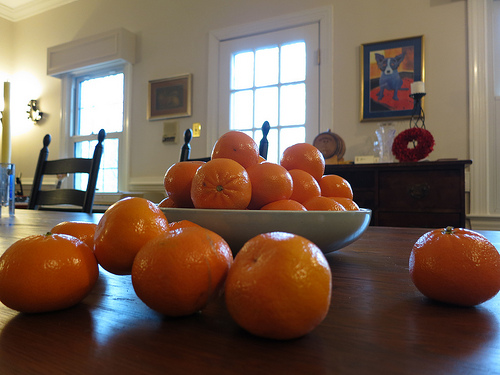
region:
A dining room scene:
[9, 11, 498, 367]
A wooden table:
[343, 275, 408, 362]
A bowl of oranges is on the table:
[156, 126, 376, 251]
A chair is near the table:
[24, 124, 112, 218]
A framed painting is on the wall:
[354, 31, 430, 125]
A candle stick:
[405, 80, 432, 131]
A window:
[42, 22, 139, 199]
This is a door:
[205, 18, 337, 161]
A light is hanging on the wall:
[16, 70, 49, 124]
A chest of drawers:
[329, 160, 488, 232]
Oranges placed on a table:
[0, 0, 498, 373]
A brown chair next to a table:
[30, 127, 105, 210]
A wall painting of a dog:
[357, 35, 427, 122]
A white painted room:
[0, 0, 497, 222]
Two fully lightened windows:
[61, 29, 312, 199]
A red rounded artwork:
[390, 125, 435, 164]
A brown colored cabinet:
[320, 159, 475, 229]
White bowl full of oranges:
[154, 194, 374, 258]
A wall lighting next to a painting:
[360, 38, 428, 125]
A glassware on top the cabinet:
[374, 119, 398, 161]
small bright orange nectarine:
[1, 225, 106, 322]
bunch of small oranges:
[0, 189, 344, 353]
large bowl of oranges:
[150, 120, 380, 280]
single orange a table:
[376, 206, 498, 318]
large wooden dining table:
[1, 184, 498, 373]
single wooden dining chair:
[18, 117, 113, 220]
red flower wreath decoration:
[381, 108, 443, 178]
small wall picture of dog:
[348, 24, 435, 131]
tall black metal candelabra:
[398, 69, 440, 136]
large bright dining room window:
[52, 55, 145, 205]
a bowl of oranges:
[125, 98, 422, 266]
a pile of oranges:
[130, 52, 372, 232]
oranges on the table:
[32, 191, 351, 371]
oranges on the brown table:
[5, 171, 344, 323]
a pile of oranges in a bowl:
[132, 106, 369, 266]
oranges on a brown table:
[93, 113, 455, 355]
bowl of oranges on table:
[132, 100, 425, 297]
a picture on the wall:
[344, 21, 458, 123]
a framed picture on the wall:
[339, 20, 440, 131]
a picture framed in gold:
[332, 29, 464, 124]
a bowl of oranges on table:
[168, 113, 376, 306]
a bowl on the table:
[190, 113, 340, 263]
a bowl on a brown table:
[114, 103, 396, 300]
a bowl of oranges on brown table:
[154, 111, 426, 325]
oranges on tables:
[22, 165, 425, 372]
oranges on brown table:
[64, 159, 365, 348]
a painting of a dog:
[358, 27, 457, 182]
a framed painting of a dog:
[353, 28, 454, 128]